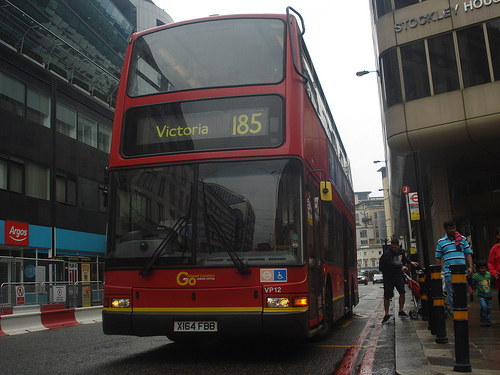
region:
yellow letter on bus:
[153, 124, 168, 136]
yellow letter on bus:
[168, 126, 179, 138]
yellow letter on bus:
[175, 123, 183, 138]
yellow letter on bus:
[179, 125, 192, 136]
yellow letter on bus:
[191, 123, 199, 137]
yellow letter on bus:
[196, 122, 203, 137]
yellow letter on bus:
[200, 122, 210, 136]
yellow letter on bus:
[176, 271, 190, 288]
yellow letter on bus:
[186, 275, 203, 287]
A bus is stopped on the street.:
[101, 7, 357, 339]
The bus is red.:
[203, 277, 251, 304]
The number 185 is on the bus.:
[229, 110, 264, 136]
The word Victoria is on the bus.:
[155, 124, 209, 137]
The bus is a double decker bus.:
[100, 5, 359, 339]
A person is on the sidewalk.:
[378, 237, 408, 323]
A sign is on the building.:
[6, 221, 28, 244]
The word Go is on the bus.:
[176, 271, 200, 289]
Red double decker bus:
[91, 4, 368, 338]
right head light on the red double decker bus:
[262, 295, 289, 310]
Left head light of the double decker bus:
[109, 295, 133, 309]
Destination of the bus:
[149, 118, 211, 142]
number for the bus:
[231, 111, 263, 138]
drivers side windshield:
[196, 163, 301, 266]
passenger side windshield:
[106, 176, 194, 265]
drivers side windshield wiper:
[204, 215, 252, 280]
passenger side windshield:
[131, 217, 186, 277]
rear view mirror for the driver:
[317, 173, 334, 201]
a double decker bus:
[88, 3, 365, 355]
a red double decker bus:
[95, 4, 366, 360]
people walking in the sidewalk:
[376, 216, 498, 345]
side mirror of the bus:
[318, 175, 333, 205]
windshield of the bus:
[101, 155, 308, 272]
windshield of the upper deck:
[121, 13, 291, 98]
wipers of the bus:
[137, 206, 254, 281]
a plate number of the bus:
[169, 317, 219, 334]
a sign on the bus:
[152, 110, 265, 140]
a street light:
[355, 67, 373, 79]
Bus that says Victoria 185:
[112, 82, 295, 164]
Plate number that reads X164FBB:
[165, 305, 242, 340]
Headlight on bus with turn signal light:
[252, 281, 314, 328]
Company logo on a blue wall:
[0, 203, 46, 265]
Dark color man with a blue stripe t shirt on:
[422, 208, 477, 294]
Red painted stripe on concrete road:
[344, 325, 399, 374]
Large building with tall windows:
[357, 10, 492, 137]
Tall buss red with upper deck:
[93, 0, 374, 350]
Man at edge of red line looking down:
[359, 235, 432, 338]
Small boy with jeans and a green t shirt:
[469, 248, 498, 330]